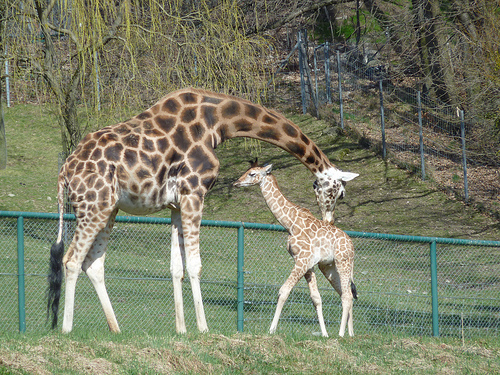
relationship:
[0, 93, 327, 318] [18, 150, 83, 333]
giraffe has tail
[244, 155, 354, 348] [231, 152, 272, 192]
giraffe has head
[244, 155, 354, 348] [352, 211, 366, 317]
giraffe has tail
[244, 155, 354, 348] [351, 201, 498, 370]
giraffe behind fence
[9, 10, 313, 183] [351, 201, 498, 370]
tree behind fence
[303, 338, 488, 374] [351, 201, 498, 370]
grass near fence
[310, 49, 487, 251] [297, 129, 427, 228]
fence on hillside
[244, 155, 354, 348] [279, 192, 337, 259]
giraffe has spots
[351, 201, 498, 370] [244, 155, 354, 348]
fence behind giraffe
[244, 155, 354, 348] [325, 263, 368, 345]
giraffe has legs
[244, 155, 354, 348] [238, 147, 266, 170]
giraffe has horns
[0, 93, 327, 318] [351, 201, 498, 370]
giraffes beside fence